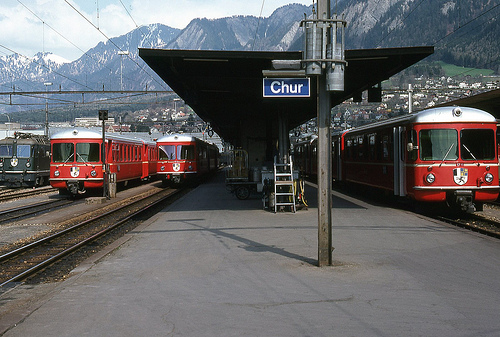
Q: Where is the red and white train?
A: At the station.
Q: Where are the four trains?
A: At the station.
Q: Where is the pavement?
A: Next to the tracks.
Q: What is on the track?
A: Train.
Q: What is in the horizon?
A: Mountains.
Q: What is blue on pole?
A: A sin.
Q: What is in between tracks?
A: Gravel.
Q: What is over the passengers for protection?
A: Awnings.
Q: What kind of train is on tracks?
A: Passenger.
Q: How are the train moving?
A: Power Lines.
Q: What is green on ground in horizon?
A: Grass.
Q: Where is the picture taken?
A: A rail station.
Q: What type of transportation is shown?
A: Trains.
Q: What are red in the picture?
A: Trains.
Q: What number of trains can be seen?
A: 4.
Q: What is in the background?
A: Mountains.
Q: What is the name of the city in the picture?
A: Chur.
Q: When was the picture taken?
A: During the day.